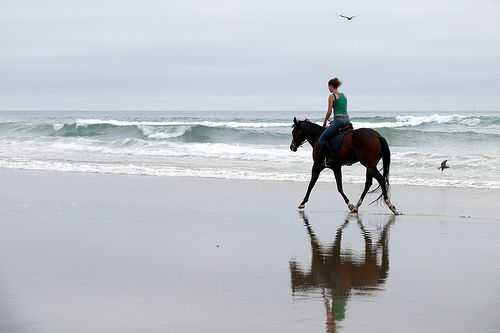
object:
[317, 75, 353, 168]
girl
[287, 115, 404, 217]
horse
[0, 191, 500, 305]
sand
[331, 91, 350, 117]
top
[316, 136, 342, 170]
boots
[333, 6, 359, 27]
bird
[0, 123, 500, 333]
beach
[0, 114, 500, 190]
waves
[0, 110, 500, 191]
water